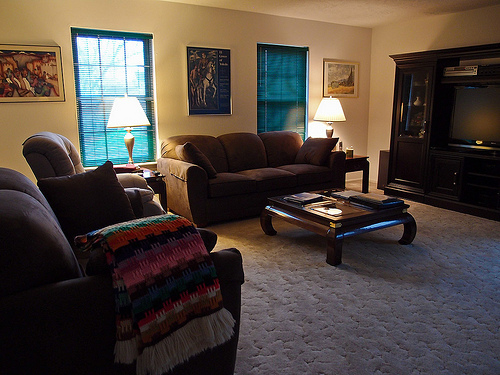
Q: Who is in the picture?
A: No one.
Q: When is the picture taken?
A: Daytime.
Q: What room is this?
A: The living room.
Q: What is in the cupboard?
A: A TV.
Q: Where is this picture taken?
A: A living room.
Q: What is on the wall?
A: A portrait.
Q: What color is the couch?
A: Brown.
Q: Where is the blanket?
A: On the chair.